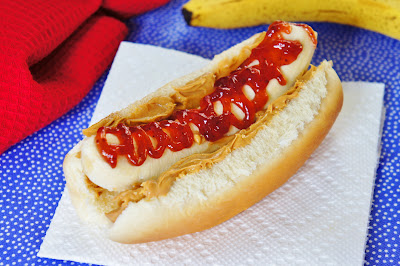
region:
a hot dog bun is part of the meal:
[68, 24, 358, 240]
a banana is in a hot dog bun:
[74, 15, 343, 242]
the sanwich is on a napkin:
[67, 29, 362, 246]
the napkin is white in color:
[35, 39, 384, 259]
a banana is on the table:
[176, 0, 399, 46]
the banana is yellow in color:
[183, 3, 395, 43]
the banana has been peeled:
[83, 27, 329, 186]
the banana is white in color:
[83, 20, 323, 190]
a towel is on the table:
[0, 0, 173, 169]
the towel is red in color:
[1, 0, 176, 154]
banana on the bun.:
[82, 21, 339, 240]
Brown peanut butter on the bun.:
[100, 68, 315, 217]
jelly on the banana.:
[102, 22, 315, 172]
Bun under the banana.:
[61, 30, 343, 243]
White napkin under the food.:
[29, 27, 390, 265]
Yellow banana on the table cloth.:
[177, 0, 398, 41]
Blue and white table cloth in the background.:
[1, 1, 399, 263]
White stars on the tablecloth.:
[2, 1, 399, 264]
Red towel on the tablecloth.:
[1, 0, 175, 156]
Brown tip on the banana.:
[178, 1, 197, 30]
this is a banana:
[48, 18, 349, 230]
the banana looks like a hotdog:
[44, 29, 370, 229]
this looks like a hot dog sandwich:
[49, 14, 373, 228]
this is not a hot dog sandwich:
[48, 37, 393, 263]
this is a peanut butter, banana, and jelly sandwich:
[53, 27, 377, 254]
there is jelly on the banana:
[74, 13, 369, 203]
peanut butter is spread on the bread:
[54, 25, 381, 264]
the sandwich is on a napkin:
[38, 16, 394, 236]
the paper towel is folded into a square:
[2, 17, 390, 263]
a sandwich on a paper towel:
[32, 4, 389, 257]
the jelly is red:
[78, 40, 305, 138]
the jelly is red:
[97, 66, 280, 163]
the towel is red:
[7, 16, 83, 124]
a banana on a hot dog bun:
[48, 12, 344, 236]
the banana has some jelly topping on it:
[100, 18, 311, 169]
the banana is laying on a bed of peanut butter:
[86, 41, 346, 206]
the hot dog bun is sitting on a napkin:
[75, 37, 357, 258]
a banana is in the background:
[192, 3, 398, 51]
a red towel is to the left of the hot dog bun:
[10, 5, 159, 148]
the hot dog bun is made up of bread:
[152, 128, 317, 196]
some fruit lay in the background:
[179, 5, 399, 59]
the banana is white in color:
[82, 140, 123, 183]